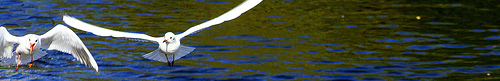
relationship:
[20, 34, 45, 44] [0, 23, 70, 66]
head on bird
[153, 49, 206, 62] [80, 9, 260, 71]
feathers on bird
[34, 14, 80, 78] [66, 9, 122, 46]
wing under wing